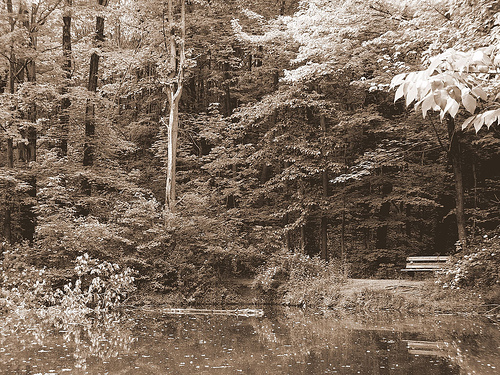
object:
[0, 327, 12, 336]
leaves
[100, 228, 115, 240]
leaves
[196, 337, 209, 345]
bubble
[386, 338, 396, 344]
bubble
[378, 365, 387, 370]
bubble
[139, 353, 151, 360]
bubble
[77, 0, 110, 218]
trunk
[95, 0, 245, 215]
tree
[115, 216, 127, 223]
leaf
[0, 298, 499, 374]
pond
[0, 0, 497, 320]
woods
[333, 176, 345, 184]
leaf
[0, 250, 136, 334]
tree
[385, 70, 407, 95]
tree leaves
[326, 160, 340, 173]
small leaf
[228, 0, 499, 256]
tree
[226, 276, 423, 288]
path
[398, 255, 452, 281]
bench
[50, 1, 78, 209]
tree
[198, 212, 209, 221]
leaf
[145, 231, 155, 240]
leaf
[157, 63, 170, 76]
leaf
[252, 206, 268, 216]
leaf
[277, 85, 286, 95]
leaf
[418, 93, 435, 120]
small leaf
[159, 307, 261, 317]
log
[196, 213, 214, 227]
leaf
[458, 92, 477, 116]
leaves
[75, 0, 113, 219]
tree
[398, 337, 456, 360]
reflection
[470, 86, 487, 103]
leaves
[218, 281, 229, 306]
person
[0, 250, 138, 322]
bush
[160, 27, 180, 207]
trunk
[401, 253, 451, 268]
back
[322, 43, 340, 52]
leaves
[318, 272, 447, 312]
area